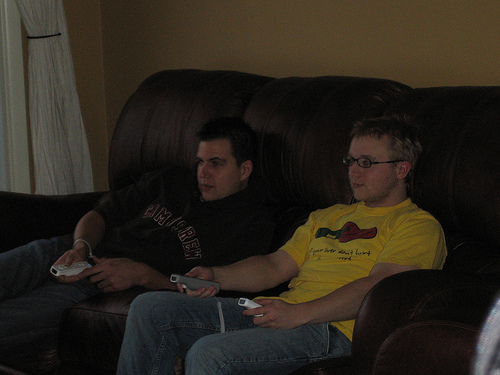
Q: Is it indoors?
A: Yes, it is indoors.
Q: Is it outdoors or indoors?
A: It is indoors.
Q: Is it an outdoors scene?
A: No, it is indoors.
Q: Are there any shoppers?
A: No, there are no shoppers.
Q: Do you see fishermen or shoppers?
A: No, there are no shoppers or fishermen.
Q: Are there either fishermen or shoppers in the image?
A: No, there are no shoppers or fishermen.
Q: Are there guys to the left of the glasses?
A: Yes, there is a guy to the left of the glasses.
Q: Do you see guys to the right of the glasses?
A: No, the guy is to the left of the glasses.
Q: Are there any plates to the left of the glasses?
A: No, there is a guy to the left of the glasses.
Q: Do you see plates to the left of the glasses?
A: No, there is a guy to the left of the glasses.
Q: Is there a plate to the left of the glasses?
A: No, there is a guy to the left of the glasses.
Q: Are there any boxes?
A: No, there are no boxes.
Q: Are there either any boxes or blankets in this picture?
A: No, there are no boxes or blankets.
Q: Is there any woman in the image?
A: No, there are no women.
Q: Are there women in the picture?
A: No, there are no women.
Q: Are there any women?
A: No, there are no women.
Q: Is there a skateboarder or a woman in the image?
A: No, there are no women or skateboarders.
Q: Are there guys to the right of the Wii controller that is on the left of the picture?
A: Yes, there is a guy to the right of the Wii controller.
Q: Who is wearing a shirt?
A: The guy is wearing a shirt.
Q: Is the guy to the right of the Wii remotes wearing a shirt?
A: Yes, the guy is wearing a shirt.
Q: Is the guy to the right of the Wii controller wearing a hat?
A: No, the guy is wearing a shirt.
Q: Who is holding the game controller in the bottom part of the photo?
A: The guy is holding the game controller.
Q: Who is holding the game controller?
A: The guy is holding the game controller.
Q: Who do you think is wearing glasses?
A: The guy is wearing glasses.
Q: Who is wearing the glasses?
A: The guy is wearing glasses.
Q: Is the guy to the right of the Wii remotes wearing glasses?
A: Yes, the guy is wearing glasses.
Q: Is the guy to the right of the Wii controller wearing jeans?
A: No, the guy is wearing glasses.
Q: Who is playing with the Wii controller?
A: The guy is playing with the Wii controller.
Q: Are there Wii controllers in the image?
A: Yes, there is a Wii controller.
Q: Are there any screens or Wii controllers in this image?
A: Yes, there is a Wii controller.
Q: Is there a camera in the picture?
A: No, there are no cameras.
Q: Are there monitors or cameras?
A: No, there are no cameras or monitors.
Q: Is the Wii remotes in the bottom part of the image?
A: Yes, the Wii remotes is in the bottom of the image.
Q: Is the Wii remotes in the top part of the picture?
A: No, the Wii remotes is in the bottom of the image.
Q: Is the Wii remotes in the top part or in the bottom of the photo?
A: The Wii remotes is in the bottom of the image.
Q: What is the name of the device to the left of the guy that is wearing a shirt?
A: The device is a Wii controller.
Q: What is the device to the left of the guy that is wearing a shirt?
A: The device is a Wii controller.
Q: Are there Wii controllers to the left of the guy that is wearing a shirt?
A: Yes, there is a Wii controller to the left of the guy.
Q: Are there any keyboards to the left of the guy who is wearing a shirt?
A: No, there is a Wii controller to the left of the guy.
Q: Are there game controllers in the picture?
A: Yes, there is a game controller.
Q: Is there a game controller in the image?
A: Yes, there is a game controller.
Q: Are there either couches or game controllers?
A: Yes, there is a game controller.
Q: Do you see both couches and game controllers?
A: Yes, there are both a game controller and a couch.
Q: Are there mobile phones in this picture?
A: No, there are no mobile phones.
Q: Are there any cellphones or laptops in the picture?
A: No, there are no cellphones or laptops.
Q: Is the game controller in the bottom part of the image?
A: Yes, the game controller is in the bottom of the image.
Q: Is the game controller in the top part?
A: No, the game controller is in the bottom of the image.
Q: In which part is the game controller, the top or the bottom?
A: The game controller is in the bottom of the image.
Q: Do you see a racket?
A: No, there are no rackets.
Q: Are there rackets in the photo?
A: No, there are no rackets.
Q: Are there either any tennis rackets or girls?
A: No, there are no tennis rackets or girls.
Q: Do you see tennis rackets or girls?
A: No, there are no tennis rackets or girls.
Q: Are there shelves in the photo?
A: No, there are no shelves.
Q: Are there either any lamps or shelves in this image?
A: No, there are no shelves or lamps.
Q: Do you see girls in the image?
A: No, there are no girls.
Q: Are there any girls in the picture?
A: No, there are no girls.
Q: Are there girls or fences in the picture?
A: No, there are no girls or fences.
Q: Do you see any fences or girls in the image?
A: No, there are no girls or fences.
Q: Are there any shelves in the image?
A: No, there are no shelves.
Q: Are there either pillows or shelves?
A: No, there are no shelves or pillows.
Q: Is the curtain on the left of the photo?
A: Yes, the curtain is on the left of the image.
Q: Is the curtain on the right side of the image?
A: No, the curtain is on the left of the image.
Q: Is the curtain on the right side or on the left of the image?
A: The curtain is on the left of the image.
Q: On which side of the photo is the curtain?
A: The curtain is on the left of the image.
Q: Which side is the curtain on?
A: The curtain is on the left of the image.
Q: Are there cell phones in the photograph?
A: No, there are no cell phones.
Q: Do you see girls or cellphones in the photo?
A: No, there are no cellphones or girls.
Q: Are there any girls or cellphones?
A: No, there are no cellphones or girls.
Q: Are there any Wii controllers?
A: Yes, there is a Wii controller.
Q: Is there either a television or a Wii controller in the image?
A: Yes, there is a Wii controller.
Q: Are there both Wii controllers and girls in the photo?
A: No, there is a Wii controller but no girls.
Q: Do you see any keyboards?
A: No, there are no keyboards.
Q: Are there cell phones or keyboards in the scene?
A: No, there are no keyboards or cell phones.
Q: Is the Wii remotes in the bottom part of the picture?
A: Yes, the Wii remotes is in the bottom of the image.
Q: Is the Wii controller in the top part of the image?
A: No, the Wii controller is in the bottom of the image.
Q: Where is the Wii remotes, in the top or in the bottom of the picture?
A: The Wii remotes is in the bottom of the image.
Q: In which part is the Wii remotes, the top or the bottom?
A: The Wii remotes is in the bottom of the image.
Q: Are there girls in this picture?
A: No, there are no girls.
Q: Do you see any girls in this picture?
A: No, there are no girls.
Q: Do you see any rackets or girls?
A: No, there are no girls or rackets.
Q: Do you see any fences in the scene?
A: No, there are no fences.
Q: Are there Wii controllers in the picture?
A: Yes, there is a Wii controller.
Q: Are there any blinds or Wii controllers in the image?
A: Yes, there is a Wii controller.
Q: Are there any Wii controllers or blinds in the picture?
A: Yes, there is a Wii controller.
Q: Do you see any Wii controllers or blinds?
A: Yes, there is a Wii controller.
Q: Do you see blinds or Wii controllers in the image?
A: Yes, there is a Wii controller.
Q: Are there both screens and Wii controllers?
A: No, there is a Wii controller but no screens.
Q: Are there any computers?
A: No, there are no computers.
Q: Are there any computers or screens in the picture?
A: No, there are no computers or screens.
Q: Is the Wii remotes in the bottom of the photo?
A: Yes, the Wii remotes is in the bottom of the image.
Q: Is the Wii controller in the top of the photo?
A: No, the Wii controller is in the bottom of the image.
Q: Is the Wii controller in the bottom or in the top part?
A: The Wii controller is in the bottom of the image.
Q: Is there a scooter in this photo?
A: No, there are no scooters.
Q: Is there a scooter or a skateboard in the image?
A: No, there are no scooters or skateboards.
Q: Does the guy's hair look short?
A: Yes, the hair is short.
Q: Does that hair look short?
A: Yes, the hair is short.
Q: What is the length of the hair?
A: The hair is short.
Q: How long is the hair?
A: The hair is short.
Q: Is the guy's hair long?
A: No, the hair is short.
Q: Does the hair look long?
A: No, the hair is short.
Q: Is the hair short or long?
A: The hair is short.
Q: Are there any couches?
A: Yes, there is a couch.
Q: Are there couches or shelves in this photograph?
A: Yes, there is a couch.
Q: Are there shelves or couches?
A: Yes, there is a couch.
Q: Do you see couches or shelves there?
A: Yes, there is a couch.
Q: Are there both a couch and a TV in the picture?
A: No, there is a couch but no televisions.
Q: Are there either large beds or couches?
A: Yes, there is a large couch.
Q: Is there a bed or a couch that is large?
A: Yes, the couch is large.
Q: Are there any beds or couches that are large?
A: Yes, the couch is large.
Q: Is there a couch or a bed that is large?
A: Yes, the couch is large.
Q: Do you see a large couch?
A: Yes, there is a large couch.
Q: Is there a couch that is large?
A: Yes, there is a couch that is large.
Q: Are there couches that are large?
A: Yes, there is a couch that is large.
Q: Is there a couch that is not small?
A: Yes, there is a large couch.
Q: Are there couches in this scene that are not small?
A: Yes, there is a large couch.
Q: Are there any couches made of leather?
A: Yes, there is a couch that is made of leather.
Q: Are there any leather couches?
A: Yes, there is a couch that is made of leather.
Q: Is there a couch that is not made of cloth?
A: Yes, there is a couch that is made of leather.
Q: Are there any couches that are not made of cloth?
A: Yes, there is a couch that is made of leather.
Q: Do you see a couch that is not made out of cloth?
A: Yes, there is a couch that is made of leather.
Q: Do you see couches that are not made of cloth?
A: Yes, there is a couch that is made of leather.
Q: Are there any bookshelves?
A: No, there are no bookshelves.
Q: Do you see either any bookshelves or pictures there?
A: No, there are no bookshelves or pictures.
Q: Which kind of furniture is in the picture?
A: The furniture is a couch.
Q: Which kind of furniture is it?
A: The piece of furniture is a couch.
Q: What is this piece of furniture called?
A: This is a couch.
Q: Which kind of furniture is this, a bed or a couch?
A: This is a couch.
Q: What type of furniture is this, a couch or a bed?
A: This is a couch.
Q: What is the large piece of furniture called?
A: The piece of furniture is a couch.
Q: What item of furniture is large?
A: The piece of furniture is a couch.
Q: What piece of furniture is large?
A: The piece of furniture is a couch.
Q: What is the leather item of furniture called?
A: The piece of furniture is a couch.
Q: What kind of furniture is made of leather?
A: The furniture is a couch.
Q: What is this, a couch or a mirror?
A: This is a couch.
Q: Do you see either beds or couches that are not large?
A: No, there is a couch but it is large.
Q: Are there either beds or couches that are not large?
A: No, there is a couch but it is large.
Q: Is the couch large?
A: Yes, the couch is large.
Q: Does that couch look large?
A: Yes, the couch is large.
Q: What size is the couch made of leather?
A: The couch is large.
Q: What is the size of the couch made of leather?
A: The couch is large.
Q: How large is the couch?
A: The couch is large.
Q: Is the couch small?
A: No, the couch is large.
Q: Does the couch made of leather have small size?
A: No, the couch is large.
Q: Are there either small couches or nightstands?
A: No, there is a couch but it is large.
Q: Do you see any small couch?
A: No, there is a couch but it is large.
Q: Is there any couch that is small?
A: No, there is a couch but it is large.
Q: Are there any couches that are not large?
A: No, there is a couch but it is large.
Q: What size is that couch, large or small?
A: The couch is large.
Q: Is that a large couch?
A: Yes, that is a large couch.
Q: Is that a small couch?
A: No, that is a large couch.